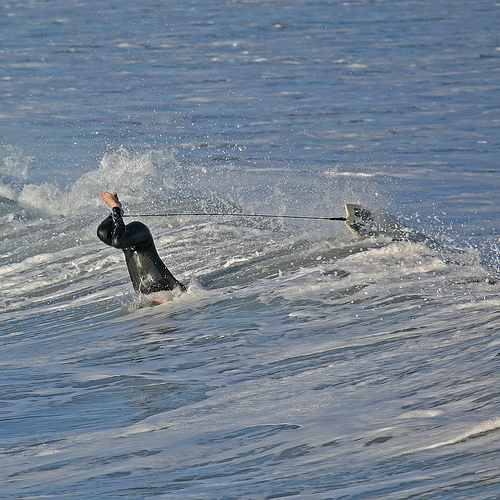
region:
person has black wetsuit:
[91, 186, 160, 322]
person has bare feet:
[90, 178, 132, 220]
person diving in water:
[93, 191, 185, 326]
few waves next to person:
[70, 163, 413, 369]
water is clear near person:
[130, 212, 332, 327]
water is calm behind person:
[260, 57, 499, 216]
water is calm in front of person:
[46, 353, 424, 483]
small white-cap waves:
[158, 176, 435, 310]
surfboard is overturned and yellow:
[205, 231, 302, 292]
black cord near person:
[66, 203, 329, 231]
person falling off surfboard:
[87, 182, 198, 324]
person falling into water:
[80, 169, 208, 334]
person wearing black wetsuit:
[75, 186, 205, 328]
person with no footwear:
[81, 179, 199, 314]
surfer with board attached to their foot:
[84, 183, 198, 313]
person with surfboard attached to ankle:
[83, 182, 205, 315]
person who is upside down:
[88, 182, 193, 310]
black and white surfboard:
[332, 190, 471, 267]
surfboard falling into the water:
[340, 196, 457, 272]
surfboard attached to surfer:
[335, 190, 476, 282]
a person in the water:
[91, 208, 198, 327]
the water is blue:
[261, 296, 449, 392]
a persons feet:
[96, 184, 127, 206]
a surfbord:
[336, 183, 436, 258]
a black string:
[177, 201, 299, 220]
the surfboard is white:
[348, 195, 405, 247]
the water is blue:
[161, 31, 378, 148]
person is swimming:
[84, 199, 190, 326]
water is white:
[347, 247, 462, 330]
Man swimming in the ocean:
[84, 188, 171, 320]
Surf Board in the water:
[325, 202, 442, 256]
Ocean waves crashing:
[68, 148, 246, 222]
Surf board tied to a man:
[114, 204, 133, 223]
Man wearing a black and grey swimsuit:
[92, 211, 184, 296]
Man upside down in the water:
[127, 251, 192, 319]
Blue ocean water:
[161, 37, 436, 144]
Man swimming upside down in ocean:
[91, 195, 184, 316]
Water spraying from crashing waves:
[91, 133, 263, 209]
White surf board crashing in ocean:
[308, 192, 434, 262]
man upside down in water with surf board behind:
[73, 179, 474, 319]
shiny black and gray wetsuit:
[112, 235, 164, 287]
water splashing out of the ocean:
[315, 245, 377, 307]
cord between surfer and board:
[121, 207, 361, 224]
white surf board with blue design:
[343, 200, 408, 247]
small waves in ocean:
[185, 109, 280, 260]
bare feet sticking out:
[88, 185, 138, 255]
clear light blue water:
[91, 361, 178, 439]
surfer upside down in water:
[88, 184, 192, 309]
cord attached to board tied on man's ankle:
[96, 185, 138, 225]